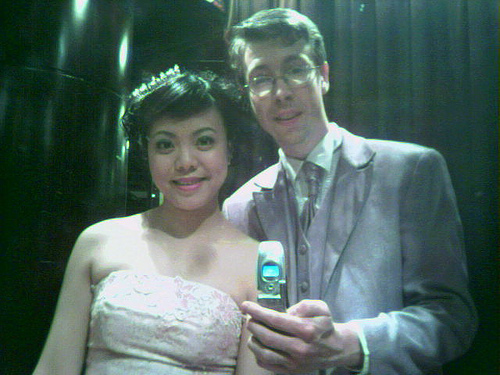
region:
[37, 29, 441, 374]
couple on a date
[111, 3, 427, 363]
a picture of a couple in a prom night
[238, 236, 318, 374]
the man holding a silver cellphone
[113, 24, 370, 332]
taking their selfie at the mirror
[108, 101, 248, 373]
the woman is wearing pink dress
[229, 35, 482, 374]
the man is wearing a purple coat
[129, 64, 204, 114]
the woman wears a crown on her head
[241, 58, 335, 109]
man is wearing eye glasses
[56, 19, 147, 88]
the reflection of the light to the wall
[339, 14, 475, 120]
the color of the curtain is maroon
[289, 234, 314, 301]
the buttons of the man's coat are also color purple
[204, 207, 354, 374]
cell phone taking picture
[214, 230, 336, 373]
cell phone being held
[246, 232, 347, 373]
flip style cell phone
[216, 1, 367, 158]
man wearing glasses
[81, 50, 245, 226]
woman wearing tiarra in hair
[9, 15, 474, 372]
couple taking photo with phone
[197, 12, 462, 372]
man wearing suit and tie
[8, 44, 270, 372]
woman wearing pink dress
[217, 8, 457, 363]
man holding flip cell phone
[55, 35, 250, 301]
woman wearing pink lipstick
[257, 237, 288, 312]
A cell phone taking a picture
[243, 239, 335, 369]
The man is holding the cell phone in his left hand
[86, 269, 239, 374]
The woman is wearing a white dress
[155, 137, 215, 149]
The eyes of the woman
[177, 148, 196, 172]
The nose of the woman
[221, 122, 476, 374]
The man is wearing a suit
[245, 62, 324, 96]
The man is wearing glasses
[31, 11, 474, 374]
Two people posing for a photo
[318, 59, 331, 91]
The left ear of the person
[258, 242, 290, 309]
The cell phone is silver